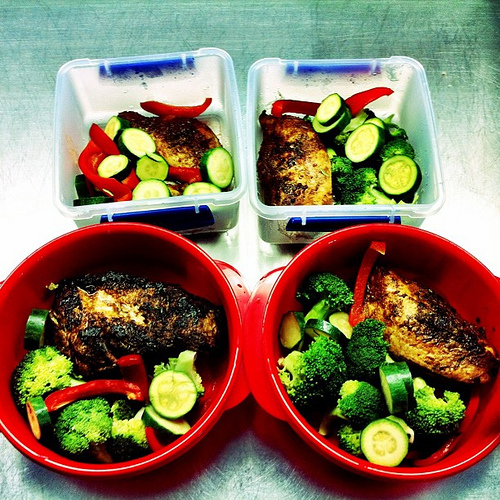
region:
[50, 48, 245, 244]
White container on the left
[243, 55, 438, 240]
White container on the right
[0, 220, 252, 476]
Red bowl on left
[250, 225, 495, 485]
Red bowl on the right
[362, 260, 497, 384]
Grilled meat in red bowl on the right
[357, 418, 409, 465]
Slice of cucumber in red bowl on the right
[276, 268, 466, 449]
Brocolli in right bowl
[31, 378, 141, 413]
Slice of red peppers in bowl on the left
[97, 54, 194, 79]
Blue handle on left plastic container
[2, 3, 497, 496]
Table bowls are sitting on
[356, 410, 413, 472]
Cucumber as part of a dish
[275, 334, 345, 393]
Broccoli as part of a dish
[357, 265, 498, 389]
Grilled chicken as part of a dish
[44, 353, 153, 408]
Red pepper as part of a dish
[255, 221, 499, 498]
Dinner in a bowl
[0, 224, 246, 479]
Meal in a bowl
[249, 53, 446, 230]
Resealable storage container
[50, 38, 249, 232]
Portable portion of a meal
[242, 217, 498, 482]
Plastic bowl with food in it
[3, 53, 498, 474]
Two servings of a meal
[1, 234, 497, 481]
two red bowls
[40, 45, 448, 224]
two containers with blue handles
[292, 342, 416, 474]
steamed broccoli and zucchini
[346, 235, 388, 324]
a slice of red pepper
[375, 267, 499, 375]
a barbecued chicken breast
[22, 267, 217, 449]
chicken breast with veggies in a red bowl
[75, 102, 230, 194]
chicken breast with broccoli, zucchini and red peppers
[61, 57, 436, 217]
two containers with chicken and vegetables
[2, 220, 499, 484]
two red bowls with chicken and veggetables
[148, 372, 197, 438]
sliced zucchini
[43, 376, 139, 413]
cooked slice of red peper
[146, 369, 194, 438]
cooked medallions of zucchini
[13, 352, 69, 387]
cooked broccoli florets in vegetable medley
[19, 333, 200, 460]
vegetable medley in a red bowl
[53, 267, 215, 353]
blackened barbecue chicken in a red bowl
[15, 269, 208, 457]
barbecue chicken with a vegetable medley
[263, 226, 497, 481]
red bowl containing chicken and vegetables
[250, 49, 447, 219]
clear square bowl with chicken and vegetables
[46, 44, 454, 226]
chicken and vegetables being packaged for lunch on the go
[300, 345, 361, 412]
broccoli cooked with other vegetables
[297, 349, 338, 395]
this is a broccoli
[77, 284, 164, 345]
this is fried beef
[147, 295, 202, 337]
the beef is brown in color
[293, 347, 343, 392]
the broccoli is green in color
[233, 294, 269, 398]
the containers are red in color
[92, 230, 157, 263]
the bowl is round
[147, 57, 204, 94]
the container is square in color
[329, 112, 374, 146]
these are cucumbers in the bowl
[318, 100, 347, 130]
the cucumber are sliced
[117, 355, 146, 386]
the pepper is red in color